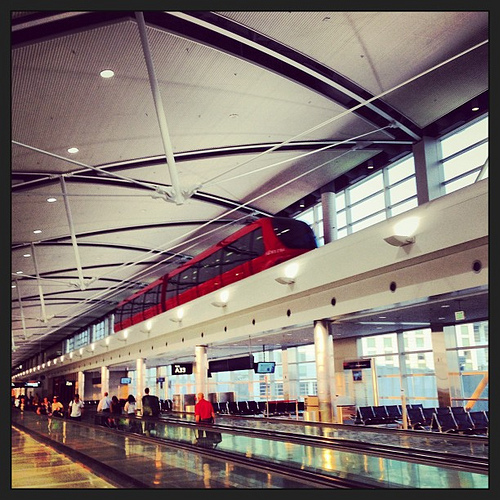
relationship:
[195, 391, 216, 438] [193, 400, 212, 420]
man wearing shirt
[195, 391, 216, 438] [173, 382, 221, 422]
man wearing shirt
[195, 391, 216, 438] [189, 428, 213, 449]
man holding bag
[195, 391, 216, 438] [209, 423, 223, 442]
man holding bag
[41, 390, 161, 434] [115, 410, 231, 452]
people walking on conveyer belt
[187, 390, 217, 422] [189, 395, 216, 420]
man wearing shirt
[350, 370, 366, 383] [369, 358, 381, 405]
tv on pole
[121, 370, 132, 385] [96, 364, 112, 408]
tv on pole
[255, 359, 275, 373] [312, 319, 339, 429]
tv on pole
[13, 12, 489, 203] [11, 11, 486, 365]
beam in ceiling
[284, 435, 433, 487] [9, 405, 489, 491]
shine on floor